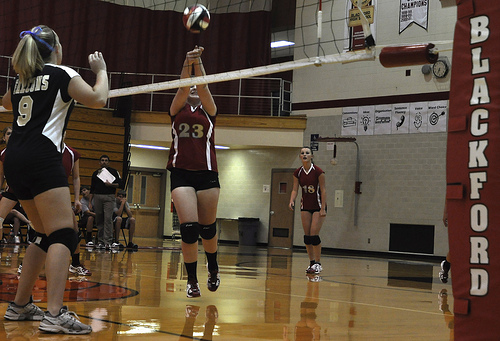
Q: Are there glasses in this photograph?
A: No, there are no glasses.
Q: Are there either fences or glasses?
A: No, there are no glasses or fences.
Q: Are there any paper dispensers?
A: No, there are no paper dispensers.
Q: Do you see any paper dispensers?
A: No, there are no paper dispensers.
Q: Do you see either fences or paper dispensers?
A: No, there are no paper dispensers or fences.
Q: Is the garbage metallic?
A: Yes, the garbage is metallic.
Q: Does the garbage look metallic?
A: Yes, the garbage is metallic.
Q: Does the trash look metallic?
A: Yes, the trash is metallic.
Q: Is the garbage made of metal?
A: Yes, the garbage is made of metal.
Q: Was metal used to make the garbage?
A: Yes, the garbage is made of metal.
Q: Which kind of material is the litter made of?
A: The litter is made of metal.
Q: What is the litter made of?
A: The litter is made of metal.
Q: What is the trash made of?
A: The litter is made of metal.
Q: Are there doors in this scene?
A: Yes, there is a door.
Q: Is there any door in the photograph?
A: Yes, there is a door.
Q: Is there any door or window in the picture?
A: Yes, there is a door.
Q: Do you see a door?
A: Yes, there is a door.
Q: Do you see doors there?
A: Yes, there is a door.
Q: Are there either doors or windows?
A: Yes, there is a door.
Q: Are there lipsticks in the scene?
A: No, there are no lipsticks.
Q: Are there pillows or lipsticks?
A: No, there are no lipsticks or pillows.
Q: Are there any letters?
A: Yes, there are letters.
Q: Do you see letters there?
A: Yes, there are letters.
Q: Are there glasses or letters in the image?
A: Yes, there are letters.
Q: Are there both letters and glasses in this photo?
A: No, there are letters but no glasses.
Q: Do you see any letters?
A: Yes, there are letters.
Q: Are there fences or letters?
A: Yes, there are letters.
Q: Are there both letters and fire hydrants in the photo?
A: No, there are letters but no fire hydrants.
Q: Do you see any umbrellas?
A: No, there are no umbrellas.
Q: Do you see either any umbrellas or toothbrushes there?
A: No, there are no umbrellas or toothbrushes.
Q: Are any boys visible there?
A: No, there are no boys.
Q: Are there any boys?
A: No, there are no boys.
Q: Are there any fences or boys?
A: No, there are no boys or fences.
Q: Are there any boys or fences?
A: No, there are no boys or fences.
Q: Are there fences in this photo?
A: No, there are no fences.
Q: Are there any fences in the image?
A: No, there are no fences.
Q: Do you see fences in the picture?
A: No, there are no fences.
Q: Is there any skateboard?
A: No, there are no skateboards.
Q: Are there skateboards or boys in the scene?
A: No, there are no skateboards or boys.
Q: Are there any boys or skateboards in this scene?
A: No, there are no skateboards or boys.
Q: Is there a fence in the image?
A: No, there are no fences.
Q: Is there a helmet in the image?
A: No, there are no helmets.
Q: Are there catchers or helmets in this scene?
A: No, there are no helmets or catchers.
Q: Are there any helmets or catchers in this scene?
A: No, there are no helmets or catchers.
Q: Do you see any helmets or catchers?
A: No, there are no helmets or catchers.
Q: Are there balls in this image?
A: Yes, there is a ball.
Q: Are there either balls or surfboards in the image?
A: Yes, there is a ball.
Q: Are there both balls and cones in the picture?
A: No, there is a ball but no cones.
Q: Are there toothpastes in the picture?
A: No, there are no toothpastes.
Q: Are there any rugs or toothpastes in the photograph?
A: No, there are no toothpastes or rugs.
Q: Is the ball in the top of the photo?
A: Yes, the ball is in the top of the image.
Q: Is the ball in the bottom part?
A: No, the ball is in the top of the image.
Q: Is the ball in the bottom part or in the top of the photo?
A: The ball is in the top of the image.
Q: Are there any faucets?
A: No, there are no faucets.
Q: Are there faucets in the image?
A: No, there are no faucets.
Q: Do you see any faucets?
A: No, there are no faucets.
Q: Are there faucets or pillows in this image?
A: No, there are no faucets or pillows.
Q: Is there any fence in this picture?
A: No, there are no fences.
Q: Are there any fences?
A: No, there are no fences.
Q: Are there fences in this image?
A: No, there are no fences.